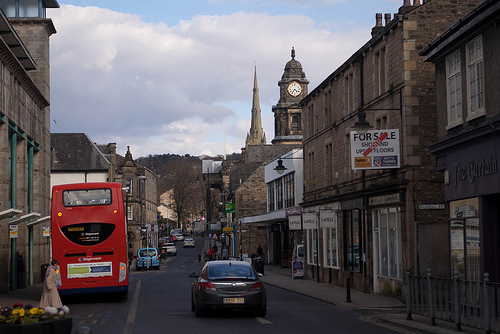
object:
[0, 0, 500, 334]
buildings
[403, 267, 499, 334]
fence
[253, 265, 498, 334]
sidewalk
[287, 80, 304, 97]
clock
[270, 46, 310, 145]
clock tower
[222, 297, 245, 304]
license plate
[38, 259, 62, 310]
woman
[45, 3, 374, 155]
clouds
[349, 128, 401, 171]
sign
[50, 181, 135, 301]
bus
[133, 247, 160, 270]
car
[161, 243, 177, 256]
car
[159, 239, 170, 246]
car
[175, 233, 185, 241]
car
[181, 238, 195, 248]
car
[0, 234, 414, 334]
street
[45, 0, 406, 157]
blue sky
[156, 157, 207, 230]
tree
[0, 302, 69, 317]
flowesr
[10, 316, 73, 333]
pot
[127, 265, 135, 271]
curb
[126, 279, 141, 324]
line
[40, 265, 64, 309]
coat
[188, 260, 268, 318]
car